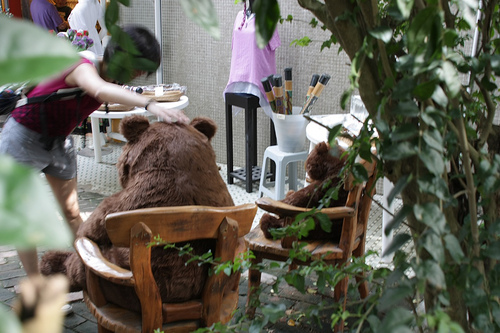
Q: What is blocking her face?
A: Leaves from the tree.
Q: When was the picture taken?
A: Daytime.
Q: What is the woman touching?
A: A stuffed animal bear.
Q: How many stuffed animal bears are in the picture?
A: Two.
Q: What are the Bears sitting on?
A: Wooden chairs.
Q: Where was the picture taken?
A: In the backyard.